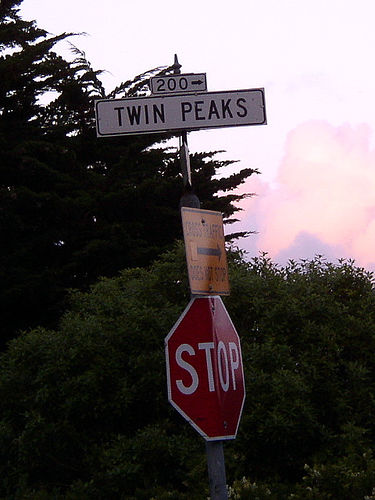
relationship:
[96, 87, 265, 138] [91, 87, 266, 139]
sign stacked on top longer sign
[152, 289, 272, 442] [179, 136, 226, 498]
sign nailed pole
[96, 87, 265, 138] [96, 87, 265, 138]
sign on sign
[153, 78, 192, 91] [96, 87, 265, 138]
200 on sign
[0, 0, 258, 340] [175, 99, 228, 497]
pine tree behind pole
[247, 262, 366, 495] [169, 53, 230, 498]
bush behind pole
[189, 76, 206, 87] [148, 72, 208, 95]
arrow on street sign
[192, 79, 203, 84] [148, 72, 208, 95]
arrow on street sign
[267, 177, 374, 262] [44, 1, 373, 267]
light in daytime sky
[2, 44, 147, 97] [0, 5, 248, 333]
branches on pine tree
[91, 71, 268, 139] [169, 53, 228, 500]
sign on pole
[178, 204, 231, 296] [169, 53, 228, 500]
sign on pole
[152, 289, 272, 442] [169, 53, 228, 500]
sign on pole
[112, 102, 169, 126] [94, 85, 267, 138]
word on sign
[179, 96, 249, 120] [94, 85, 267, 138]
word on sign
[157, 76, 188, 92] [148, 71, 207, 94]
200 on sign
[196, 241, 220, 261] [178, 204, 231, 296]
arrow on sign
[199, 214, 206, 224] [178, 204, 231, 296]
bolt on sign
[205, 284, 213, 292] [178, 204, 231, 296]
bolt on sign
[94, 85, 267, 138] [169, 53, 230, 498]
sign on pole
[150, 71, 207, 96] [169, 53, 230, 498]
sign on pole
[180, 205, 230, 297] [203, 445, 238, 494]
sign on pole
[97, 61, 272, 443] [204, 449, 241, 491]
sign on post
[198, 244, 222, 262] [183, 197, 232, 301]
arrow on sign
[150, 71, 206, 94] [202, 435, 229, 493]
sign on pole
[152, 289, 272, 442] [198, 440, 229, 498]
sign on pole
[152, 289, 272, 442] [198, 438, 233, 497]
sign on pole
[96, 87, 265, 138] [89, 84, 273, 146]
sign on sign